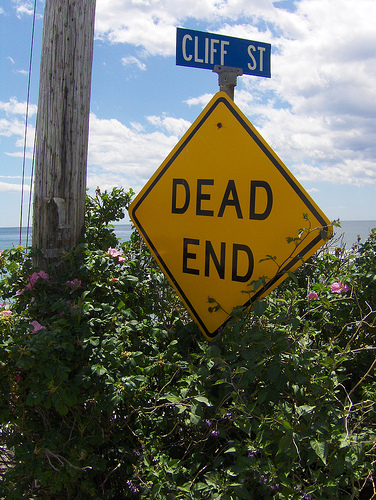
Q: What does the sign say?
A: Dead end.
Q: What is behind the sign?
A: Ocean.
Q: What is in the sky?
A: Clouds.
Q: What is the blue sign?
A: Street sign.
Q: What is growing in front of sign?
A: Bush.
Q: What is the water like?
A: Flat.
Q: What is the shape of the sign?
A: Diamond.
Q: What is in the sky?
A: Clouds.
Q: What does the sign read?
A: Dead End.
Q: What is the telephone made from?
A: Wood.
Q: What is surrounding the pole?
A: Plants.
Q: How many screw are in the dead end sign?
A: 2.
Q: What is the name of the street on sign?
A: Cliff.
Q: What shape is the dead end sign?
A: Diamond.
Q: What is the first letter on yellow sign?
A: D.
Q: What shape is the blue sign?
A: Rectangle.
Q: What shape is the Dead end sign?
A: Diamond.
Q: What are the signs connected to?
A: A metal pole.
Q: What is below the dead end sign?
A: Plants.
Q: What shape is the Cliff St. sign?
A: Rectangle.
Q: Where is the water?
A: Beyond the signs.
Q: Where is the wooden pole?
A: On the left.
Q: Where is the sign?
A: Among the plants.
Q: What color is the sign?
A: Black and yellow.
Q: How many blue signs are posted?
A: 1.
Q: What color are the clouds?
A: White.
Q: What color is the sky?
A: Blue.